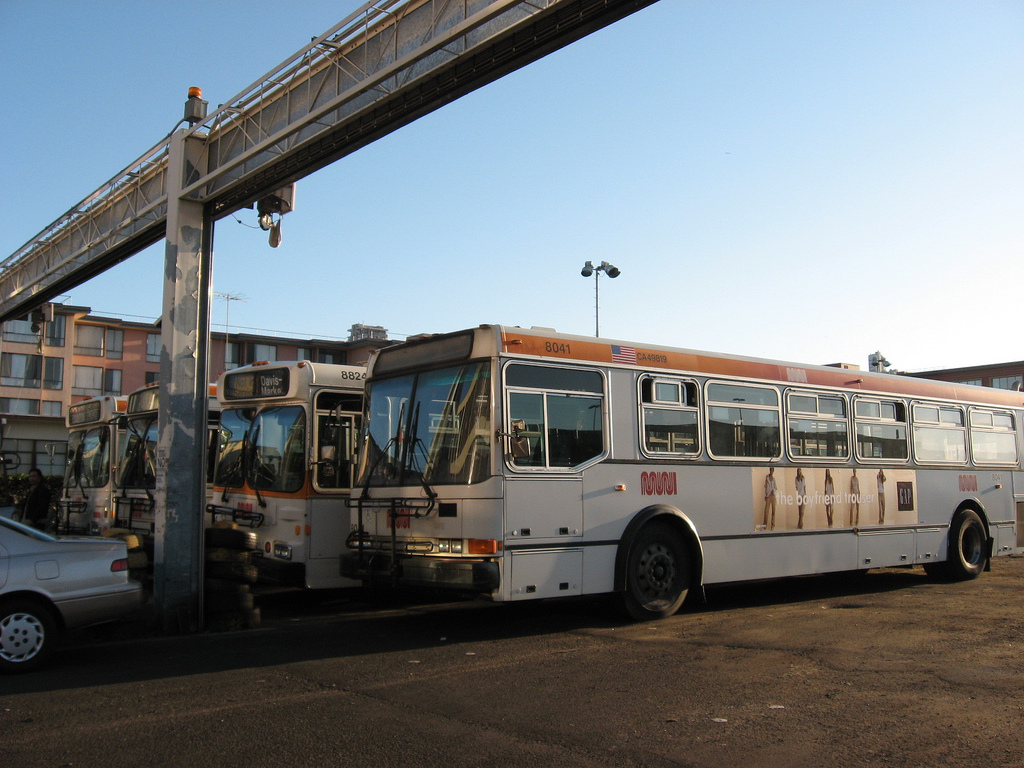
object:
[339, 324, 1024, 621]
bus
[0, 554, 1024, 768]
road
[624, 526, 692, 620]
wheel